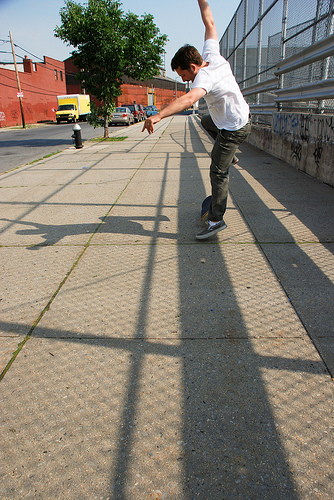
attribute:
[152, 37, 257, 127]
t-shirt — white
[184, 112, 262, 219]
pants — green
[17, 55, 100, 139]
walls — red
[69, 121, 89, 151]
hydrant — white, black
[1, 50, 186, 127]
building — red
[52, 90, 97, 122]
truck — yellow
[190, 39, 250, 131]
shirt — white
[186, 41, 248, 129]
shirt — white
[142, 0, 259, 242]
man — skateboarding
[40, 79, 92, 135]
truck — yellow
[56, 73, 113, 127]
truck — yellow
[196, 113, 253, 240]
pants — brown